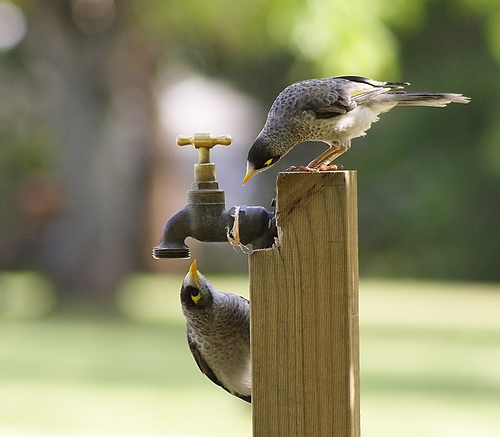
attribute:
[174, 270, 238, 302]
eye — dark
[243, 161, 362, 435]
post — wood, wooden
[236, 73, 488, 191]
bird — black, white, one, on top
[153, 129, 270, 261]
tap — black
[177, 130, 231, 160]
handle — golden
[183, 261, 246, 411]
bird — black, white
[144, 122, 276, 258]
handle — brass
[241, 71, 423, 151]
bird — gray, white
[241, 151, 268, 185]
beak — yellow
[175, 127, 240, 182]
handle — gold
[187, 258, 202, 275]
beak — yellow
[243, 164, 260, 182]
beak — yellow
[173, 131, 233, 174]
spigot — brass